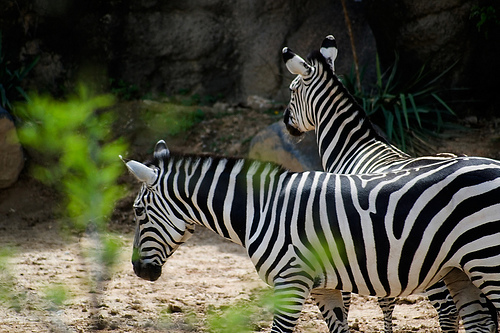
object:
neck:
[166, 151, 279, 243]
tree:
[17, 79, 124, 228]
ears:
[318, 35, 341, 66]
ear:
[281, 45, 313, 72]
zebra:
[118, 137, 498, 332]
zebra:
[283, 34, 498, 332]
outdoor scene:
[1, 0, 498, 330]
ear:
[118, 153, 158, 185]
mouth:
[132, 260, 160, 280]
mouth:
[280, 114, 301, 135]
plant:
[354, 62, 459, 144]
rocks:
[3, 113, 22, 184]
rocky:
[234, 0, 376, 110]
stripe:
[340, 174, 378, 298]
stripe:
[292, 87, 311, 129]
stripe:
[135, 226, 179, 249]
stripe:
[340, 125, 377, 156]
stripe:
[457, 237, 499, 267]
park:
[11, 15, 497, 331]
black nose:
[131, 258, 141, 273]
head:
[284, 45, 338, 136]